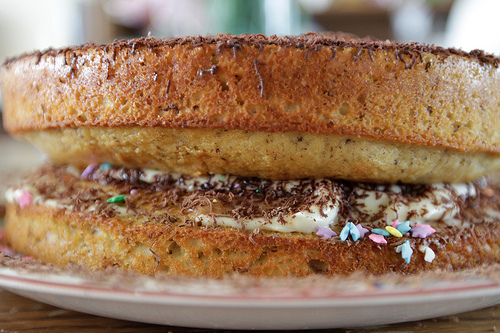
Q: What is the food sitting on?
A: A plate.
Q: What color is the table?
A: Brown.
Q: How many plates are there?
A: One.